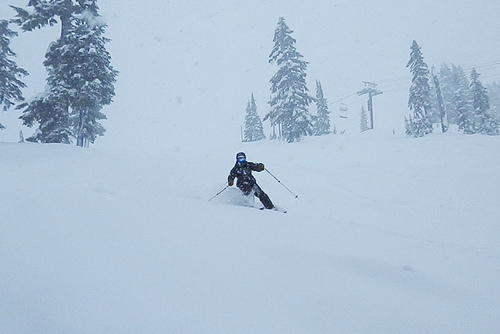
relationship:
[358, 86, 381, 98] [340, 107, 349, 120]
tower suspending chairlift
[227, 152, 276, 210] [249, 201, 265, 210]
person that on ski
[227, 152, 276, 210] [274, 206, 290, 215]
person that on ski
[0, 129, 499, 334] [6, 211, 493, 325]
ground covered in snow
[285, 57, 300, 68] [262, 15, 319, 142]
snow covering tree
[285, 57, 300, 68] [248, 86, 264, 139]
snow covering tree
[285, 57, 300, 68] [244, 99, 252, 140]
snow covering tree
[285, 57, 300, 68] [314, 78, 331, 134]
snow covering tree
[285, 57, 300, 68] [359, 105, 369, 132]
snow covering tree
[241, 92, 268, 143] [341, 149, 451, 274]
pine tree in back with a lot of snow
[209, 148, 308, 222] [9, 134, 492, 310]
person skiing snow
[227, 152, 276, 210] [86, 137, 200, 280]
person skiing hill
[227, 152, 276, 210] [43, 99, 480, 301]
person skiing on mountain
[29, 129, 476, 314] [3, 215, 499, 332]
ground covered in snow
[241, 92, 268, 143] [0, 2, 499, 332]
pine tree covered in snow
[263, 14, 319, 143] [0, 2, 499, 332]
evergreen tree covered in snow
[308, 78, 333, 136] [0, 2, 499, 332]
pine tree covered in snow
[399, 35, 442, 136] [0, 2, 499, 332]
evergreen tree covered in snow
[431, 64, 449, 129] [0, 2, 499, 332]
tree covered in snow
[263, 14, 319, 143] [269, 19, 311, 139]
evergreen tree covered in snow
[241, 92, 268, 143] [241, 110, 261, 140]
pine tree covered in snow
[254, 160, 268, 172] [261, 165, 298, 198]
hand holding holding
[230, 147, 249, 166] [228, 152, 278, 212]
head of person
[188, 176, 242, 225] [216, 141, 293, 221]
snow behind skier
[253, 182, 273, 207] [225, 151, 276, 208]
leg of person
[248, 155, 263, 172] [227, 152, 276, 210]
arm of person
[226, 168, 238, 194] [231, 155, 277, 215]
arm of person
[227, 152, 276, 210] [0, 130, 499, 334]
person skiing on hill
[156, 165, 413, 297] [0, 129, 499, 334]
snow covering ground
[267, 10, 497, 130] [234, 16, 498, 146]
snow covering trees